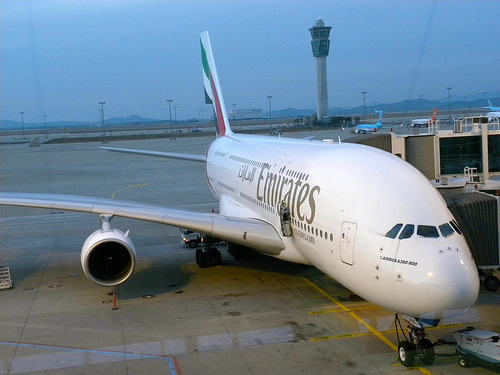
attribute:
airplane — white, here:
[0, 31, 500, 367]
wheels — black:
[400, 339, 435, 366]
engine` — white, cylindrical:
[80, 229, 137, 289]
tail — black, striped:
[200, 30, 233, 137]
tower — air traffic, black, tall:
[309, 19, 333, 125]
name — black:
[257, 164, 323, 225]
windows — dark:
[385, 220, 461, 240]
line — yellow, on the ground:
[414, 360, 430, 373]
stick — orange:
[430, 106, 439, 131]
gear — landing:
[394, 315, 434, 365]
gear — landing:
[195, 235, 221, 267]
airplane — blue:
[352, 114, 385, 135]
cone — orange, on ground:
[210, 205, 216, 213]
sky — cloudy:
[2, 0, 496, 121]